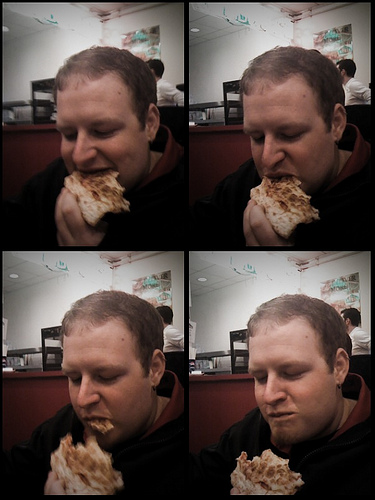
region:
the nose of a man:
[255, 135, 300, 184]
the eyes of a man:
[245, 344, 346, 392]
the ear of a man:
[316, 332, 367, 386]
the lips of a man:
[265, 407, 305, 426]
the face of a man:
[238, 294, 354, 452]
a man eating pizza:
[230, 75, 351, 240]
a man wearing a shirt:
[216, 297, 367, 483]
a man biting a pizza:
[32, 82, 188, 232]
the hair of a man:
[49, 290, 211, 386]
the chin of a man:
[261, 427, 315, 463]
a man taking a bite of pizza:
[49, 46, 177, 249]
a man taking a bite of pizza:
[208, 48, 373, 247]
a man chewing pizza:
[2, 293, 182, 497]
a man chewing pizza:
[193, 293, 373, 496]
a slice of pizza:
[227, 446, 302, 499]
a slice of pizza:
[50, 434, 121, 495]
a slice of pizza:
[252, 176, 320, 234]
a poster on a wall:
[314, 24, 354, 69]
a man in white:
[339, 307, 374, 355]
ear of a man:
[149, 347, 165, 389]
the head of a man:
[216, 40, 355, 212]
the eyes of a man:
[47, 366, 161, 405]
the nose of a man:
[65, 131, 106, 172]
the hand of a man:
[45, 179, 131, 235]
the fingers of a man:
[54, 178, 130, 242]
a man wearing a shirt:
[202, 41, 373, 239]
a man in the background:
[305, 28, 371, 148]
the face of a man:
[53, 288, 191, 435]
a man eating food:
[0, 45, 175, 240]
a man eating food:
[185, 45, 365, 240]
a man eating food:
[0, 289, 180, 492]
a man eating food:
[186, 289, 367, 492]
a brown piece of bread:
[61, 166, 125, 220]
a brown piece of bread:
[248, 173, 318, 234]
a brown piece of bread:
[48, 432, 120, 488]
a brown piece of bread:
[229, 445, 301, 490]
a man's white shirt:
[345, 78, 370, 101]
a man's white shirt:
[353, 326, 371, 353]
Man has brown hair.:
[64, 46, 137, 92]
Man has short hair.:
[62, 295, 159, 361]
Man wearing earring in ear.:
[144, 377, 170, 403]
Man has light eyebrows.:
[45, 355, 130, 378]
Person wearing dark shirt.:
[144, 436, 184, 481]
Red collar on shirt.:
[158, 390, 188, 427]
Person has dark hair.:
[156, 303, 178, 326]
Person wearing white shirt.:
[164, 322, 180, 353]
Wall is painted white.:
[15, 294, 60, 328]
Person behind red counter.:
[201, 389, 223, 413]